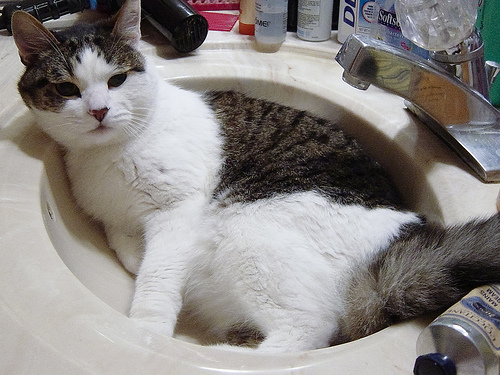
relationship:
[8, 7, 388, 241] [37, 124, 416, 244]
cat in sink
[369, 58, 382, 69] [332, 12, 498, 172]
chrome bathroom faucet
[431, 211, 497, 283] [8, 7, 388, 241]
tail of cat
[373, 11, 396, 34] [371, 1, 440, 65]
pump hand soap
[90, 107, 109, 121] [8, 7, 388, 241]
nose of cat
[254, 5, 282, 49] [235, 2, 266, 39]
tube of cream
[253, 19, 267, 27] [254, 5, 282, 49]
black on tube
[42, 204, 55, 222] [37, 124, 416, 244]
hole of sink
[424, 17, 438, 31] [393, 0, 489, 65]
plastic faucet knob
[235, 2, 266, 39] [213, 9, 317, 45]
cream on counter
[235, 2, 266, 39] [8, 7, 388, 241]
cream by cat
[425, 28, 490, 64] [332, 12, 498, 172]
knob on faucet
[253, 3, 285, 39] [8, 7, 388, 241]
bottle by cat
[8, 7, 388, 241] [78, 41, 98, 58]
cat with fur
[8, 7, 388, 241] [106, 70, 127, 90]
cat with eye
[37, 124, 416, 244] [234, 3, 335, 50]
sink by products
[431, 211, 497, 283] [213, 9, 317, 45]
tail on counter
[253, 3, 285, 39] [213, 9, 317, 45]
bottle on counter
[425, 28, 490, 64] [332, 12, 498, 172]
knob for faucet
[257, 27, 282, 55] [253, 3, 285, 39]
bottom of bottle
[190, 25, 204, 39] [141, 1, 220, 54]
vents on dryer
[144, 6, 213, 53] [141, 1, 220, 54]
knozzle of dryer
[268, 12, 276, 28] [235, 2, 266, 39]
silver tube cream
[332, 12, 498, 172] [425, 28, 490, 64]
faucet with knob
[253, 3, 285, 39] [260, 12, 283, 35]
bottle with liquid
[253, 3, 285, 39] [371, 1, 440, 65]
bottle of soap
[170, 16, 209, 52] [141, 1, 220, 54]
end of dryer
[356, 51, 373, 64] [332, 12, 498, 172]
reflection on faucet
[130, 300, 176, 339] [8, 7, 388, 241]
paw of cat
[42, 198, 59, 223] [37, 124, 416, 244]
hole in sink